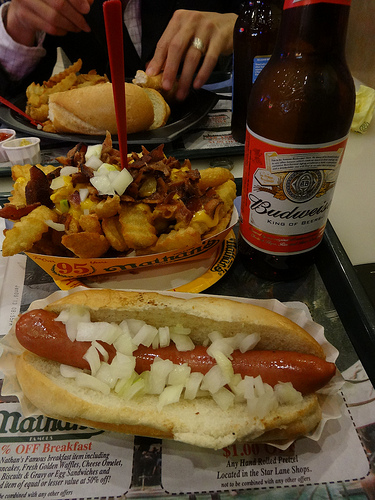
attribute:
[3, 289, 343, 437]
hot dog — full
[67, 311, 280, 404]
onions — chopped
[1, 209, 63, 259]
fry — crinkle cut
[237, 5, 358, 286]
bottle — of budweiser beer, glass, brown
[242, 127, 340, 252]
label — red, white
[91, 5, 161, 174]
fork — red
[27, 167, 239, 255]
fries — loaded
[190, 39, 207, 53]
ring — gold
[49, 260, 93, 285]
number — 95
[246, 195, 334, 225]
writing — black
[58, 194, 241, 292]
plate — yellow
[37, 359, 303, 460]
bun — toasted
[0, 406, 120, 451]
company name — green, white